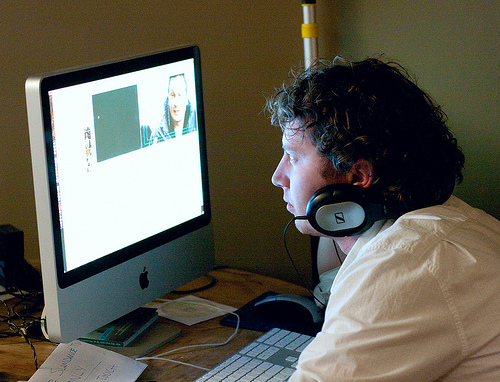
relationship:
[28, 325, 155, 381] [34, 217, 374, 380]
paper on desk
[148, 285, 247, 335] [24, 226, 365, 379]
cd on desk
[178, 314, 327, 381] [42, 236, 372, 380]
keyboard on desk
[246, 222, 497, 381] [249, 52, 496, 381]
shirt on man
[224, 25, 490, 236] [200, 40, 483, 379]
hair on man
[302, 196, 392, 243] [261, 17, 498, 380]
headphones on man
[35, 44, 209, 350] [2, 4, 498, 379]
computer screen in room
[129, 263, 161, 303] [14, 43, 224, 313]
apple on monitor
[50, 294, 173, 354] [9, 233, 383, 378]
book on desk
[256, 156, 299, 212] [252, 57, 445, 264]
nose on face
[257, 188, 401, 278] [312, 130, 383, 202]
headphone below ear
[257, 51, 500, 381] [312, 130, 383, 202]
man has an ear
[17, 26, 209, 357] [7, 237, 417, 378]
monitor on desk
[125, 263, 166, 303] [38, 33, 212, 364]
logo on monitor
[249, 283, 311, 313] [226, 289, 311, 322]
mouse on pad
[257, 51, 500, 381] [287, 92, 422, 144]
man with hair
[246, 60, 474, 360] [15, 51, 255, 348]
man focused montor